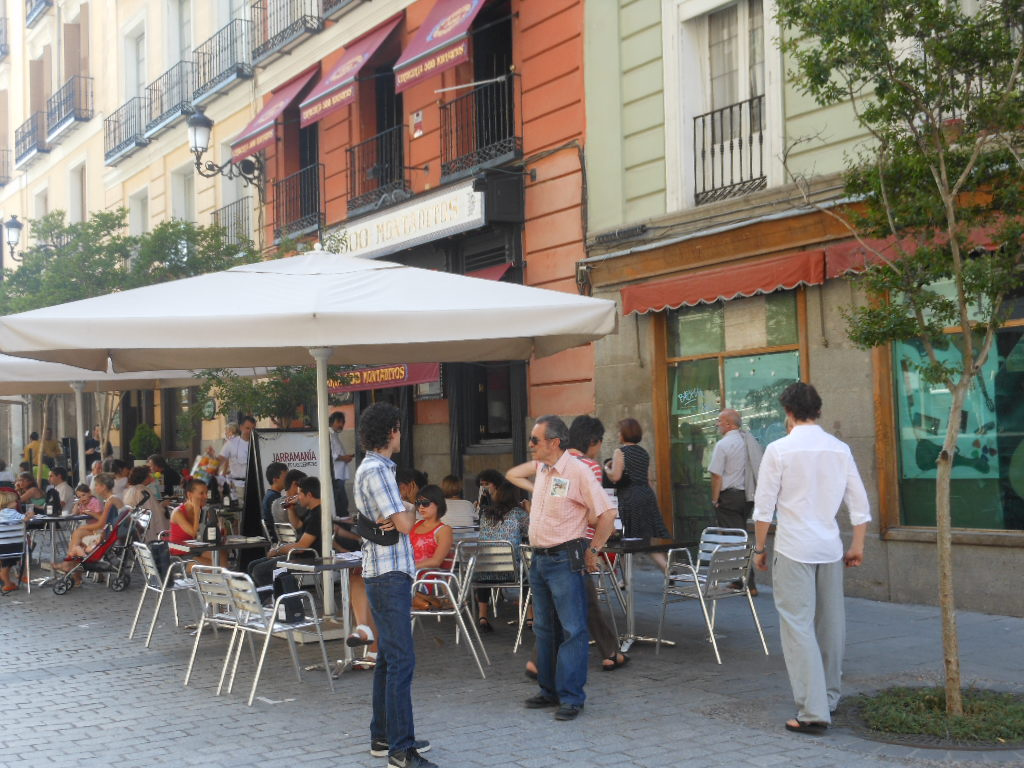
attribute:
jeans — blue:
[526, 529, 596, 702]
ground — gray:
[6, 521, 1022, 766]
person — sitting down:
[344, 476, 465, 667]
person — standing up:
[475, 409, 625, 725]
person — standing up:
[346, 390, 459, 760]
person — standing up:
[585, 402, 696, 612]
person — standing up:
[694, 394, 768, 598]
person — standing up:
[743, 374, 873, 744]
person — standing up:
[203, 411, 268, 554]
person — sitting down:
[153, 474, 227, 580]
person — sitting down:
[326, 476, 463, 671]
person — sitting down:
[464, 461, 534, 622]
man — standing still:
[344, 405, 440, 747]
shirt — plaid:
[348, 456, 426, 590]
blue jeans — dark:
[361, 543, 426, 758]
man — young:
[353, 396, 429, 757]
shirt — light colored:
[523, 456, 612, 550]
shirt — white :
[746, 424, 876, 567]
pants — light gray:
[765, 539, 848, 721]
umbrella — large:
[27, 264, 624, 640]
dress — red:
[413, 523, 444, 554]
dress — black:
[612, 443, 662, 541]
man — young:
[279, 480, 321, 556]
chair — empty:
[672, 502, 765, 656]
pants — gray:
[770, 550, 850, 723]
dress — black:
[619, 450, 665, 541]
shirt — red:
[414, 522, 441, 598]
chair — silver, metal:
[212, 556, 349, 729]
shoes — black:
[526, 679, 598, 734]